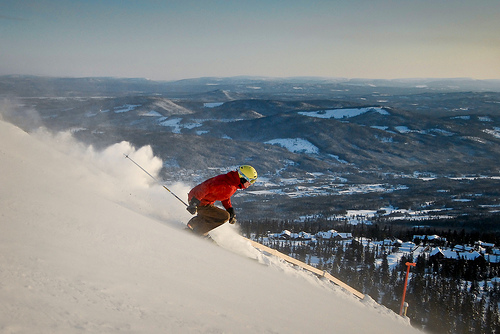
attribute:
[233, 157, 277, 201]
helmet — yellow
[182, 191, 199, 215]
glove — black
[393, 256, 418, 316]
pole — red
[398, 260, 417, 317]
pole — red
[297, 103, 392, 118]
snow — flying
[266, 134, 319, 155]
snow — flying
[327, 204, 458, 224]
snow — flying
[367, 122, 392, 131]
snow — flying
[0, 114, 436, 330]
snow — flying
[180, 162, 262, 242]
person — experienced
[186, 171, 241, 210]
jacket — red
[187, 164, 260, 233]
skier — crouched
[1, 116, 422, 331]
hill — steep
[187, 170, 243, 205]
coat — red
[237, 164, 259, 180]
helmet — yellow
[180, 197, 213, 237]
pants — black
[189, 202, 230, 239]
pants — brown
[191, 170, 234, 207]
jacket — red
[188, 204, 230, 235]
pants — brown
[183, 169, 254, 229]
person — skiing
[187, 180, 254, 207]
jacket — red